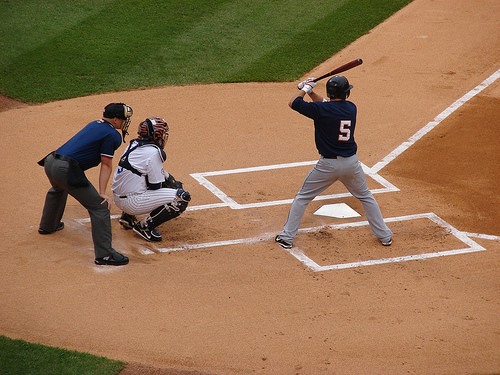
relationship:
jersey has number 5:
[290, 96, 359, 159] [336, 118, 353, 143]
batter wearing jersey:
[272, 75, 395, 249] [290, 96, 359, 159]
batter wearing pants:
[272, 75, 395, 249] [279, 152, 394, 247]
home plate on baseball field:
[311, 200, 362, 219] [0, 0, 498, 373]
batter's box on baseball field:
[274, 211, 488, 274] [0, 0, 498, 373]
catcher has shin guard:
[111, 114, 192, 244] [148, 200, 189, 233]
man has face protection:
[38, 102, 133, 266] [120, 105, 134, 143]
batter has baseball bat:
[272, 75, 395, 249] [297, 59, 366, 91]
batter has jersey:
[272, 75, 395, 249] [291, 96, 357, 158]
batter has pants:
[272, 75, 395, 249] [279, 152, 394, 247]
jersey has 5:
[291, 96, 357, 158] [336, 118, 353, 143]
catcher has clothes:
[111, 114, 192, 244] [109, 140, 177, 214]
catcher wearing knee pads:
[111, 114, 192, 244] [175, 188, 192, 213]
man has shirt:
[35, 102, 132, 268] [56, 117, 123, 171]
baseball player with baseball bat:
[272, 75, 395, 249] [297, 59, 366, 91]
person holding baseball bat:
[272, 75, 395, 249] [304, 59, 366, 85]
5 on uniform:
[336, 118, 353, 143] [279, 96, 393, 247]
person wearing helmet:
[272, 75, 395, 249] [324, 74, 355, 101]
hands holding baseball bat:
[296, 75, 316, 94] [297, 59, 366, 91]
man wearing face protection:
[38, 102, 133, 266] [120, 102, 136, 143]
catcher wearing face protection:
[111, 116, 192, 241] [136, 115, 171, 150]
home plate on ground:
[311, 200, 362, 219] [2, 1, 500, 374]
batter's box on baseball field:
[186, 153, 404, 213] [1, 1, 498, 374]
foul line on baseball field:
[370, 68, 499, 172] [1, 1, 498, 374]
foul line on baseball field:
[460, 227, 499, 246] [1, 1, 498, 374]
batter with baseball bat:
[272, 75, 395, 249] [297, 59, 366, 91]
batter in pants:
[272, 75, 395, 249] [279, 152, 394, 247]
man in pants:
[35, 102, 132, 268] [37, 151, 113, 259]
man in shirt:
[35, 102, 132, 268] [56, 117, 123, 171]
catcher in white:
[111, 116, 192, 241] [109, 140, 177, 214]